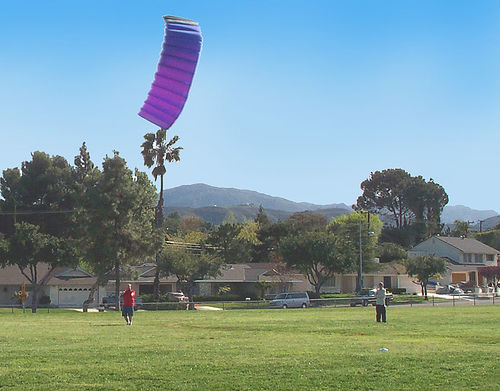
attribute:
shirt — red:
[119, 288, 137, 306]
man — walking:
[113, 281, 138, 325]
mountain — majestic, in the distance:
[150, 178, 499, 230]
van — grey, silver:
[267, 290, 311, 311]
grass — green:
[3, 306, 498, 391]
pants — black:
[373, 304, 389, 323]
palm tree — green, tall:
[139, 126, 186, 225]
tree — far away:
[352, 163, 448, 235]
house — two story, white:
[404, 228, 497, 279]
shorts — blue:
[117, 302, 136, 318]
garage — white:
[52, 285, 101, 308]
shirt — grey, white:
[373, 288, 388, 307]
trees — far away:
[145, 207, 496, 266]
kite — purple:
[139, 14, 201, 128]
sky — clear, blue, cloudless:
[208, 9, 489, 161]